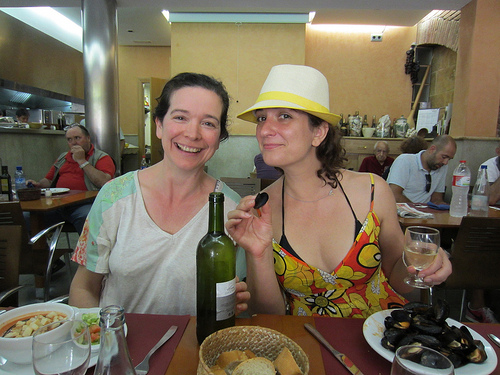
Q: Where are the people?
A: A restaurant.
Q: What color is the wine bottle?
A: Green.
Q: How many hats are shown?
A: One.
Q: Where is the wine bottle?
A: On table.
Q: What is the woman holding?
A: Wine glass.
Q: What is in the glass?
A: Wine.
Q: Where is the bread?
A: Basket.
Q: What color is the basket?
A: Tan.